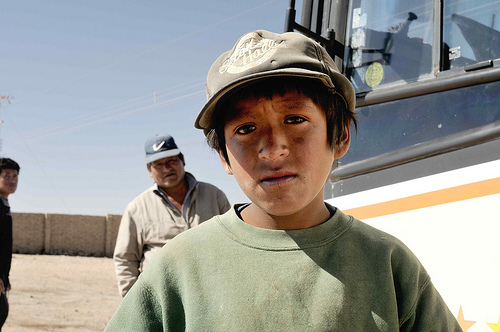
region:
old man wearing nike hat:
[111, 133, 231, 299]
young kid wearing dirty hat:
[102, 30, 462, 330]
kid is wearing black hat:
[193, 28, 355, 133]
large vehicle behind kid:
[286, 3, 499, 330]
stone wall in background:
[9, 210, 123, 257]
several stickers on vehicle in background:
[343, 5, 388, 85]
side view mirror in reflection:
[283, 0, 430, 84]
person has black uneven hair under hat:
[198, 73, 359, 167]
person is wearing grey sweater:
[100, 198, 462, 330]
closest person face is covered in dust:
[218, 92, 337, 227]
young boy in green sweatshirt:
[100, 28, 471, 329]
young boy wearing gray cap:
[96, 27, 466, 330]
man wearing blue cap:
[108, 134, 232, 297]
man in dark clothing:
[1, 157, 21, 329]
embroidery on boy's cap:
[218, 30, 278, 75]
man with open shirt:
[108, 133, 230, 306]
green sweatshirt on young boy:
[98, 203, 463, 330]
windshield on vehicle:
[332, 0, 499, 102]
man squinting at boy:
[110, 132, 231, 307]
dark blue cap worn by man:
[141, 131, 182, 163]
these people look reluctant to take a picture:
[17, 12, 476, 315]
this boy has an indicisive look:
[171, 31, 380, 231]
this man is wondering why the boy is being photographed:
[118, 126, 203, 206]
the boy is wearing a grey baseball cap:
[187, 15, 369, 136]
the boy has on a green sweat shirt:
[115, 208, 464, 330]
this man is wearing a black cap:
[144, 133, 191, 187]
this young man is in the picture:
[0, 149, 27, 329]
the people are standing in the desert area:
[3, 144, 190, 328]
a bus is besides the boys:
[278, 3, 499, 240]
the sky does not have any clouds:
[3, 13, 277, 203]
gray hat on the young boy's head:
[183, 27, 358, 129]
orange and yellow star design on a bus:
[457, 305, 499, 330]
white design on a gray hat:
[221, 31, 292, 76]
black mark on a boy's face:
[292, 134, 304, 147]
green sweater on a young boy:
[103, 199, 466, 330]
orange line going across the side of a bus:
[344, 176, 498, 223]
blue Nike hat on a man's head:
[142, 135, 182, 166]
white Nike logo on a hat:
[148, 135, 168, 152]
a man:
[2, 153, 21, 330]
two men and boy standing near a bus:
[1, 1, 497, 330]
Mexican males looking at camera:
[0, 21, 377, 268]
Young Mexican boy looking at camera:
[213, 48, 340, 231]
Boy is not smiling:
[188, 39, 373, 238]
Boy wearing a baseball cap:
[203, 0, 346, 205]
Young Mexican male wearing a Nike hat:
[126, 101, 222, 237]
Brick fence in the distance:
[10, 201, 106, 266]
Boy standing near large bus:
[270, 1, 490, 246]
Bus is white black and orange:
[360, 7, 495, 262]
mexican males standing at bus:
[5, 16, 380, 288]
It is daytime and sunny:
[0, 11, 319, 284]